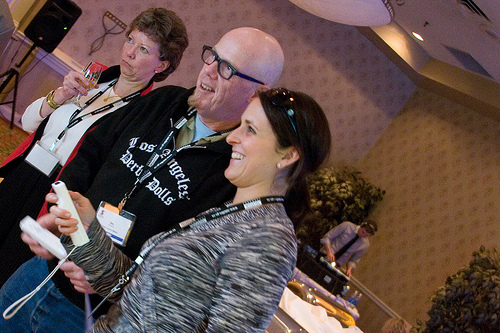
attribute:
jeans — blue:
[11, 260, 48, 327]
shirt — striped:
[58, 202, 296, 331]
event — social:
[2, 5, 498, 328]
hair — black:
[278, 92, 356, 159]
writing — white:
[118, 132, 198, 205]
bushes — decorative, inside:
[420, 241, 497, 330]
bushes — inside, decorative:
[303, 164, 383, 218]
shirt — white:
[8, 40, 150, 167]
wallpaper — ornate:
[1, 0, 499, 330]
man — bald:
[315, 210, 379, 282]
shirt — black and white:
[151, 200, 291, 331]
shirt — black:
[59, 83, 223, 224]